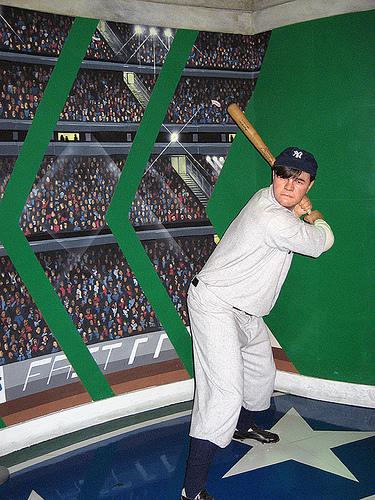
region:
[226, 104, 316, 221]
the statue is a baseball player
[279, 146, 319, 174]
the statue has a hat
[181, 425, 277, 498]
the statue is wearing shoes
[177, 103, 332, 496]
the statue is of a famous player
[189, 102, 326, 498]
the statue is on a batters position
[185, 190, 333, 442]
the uniform is white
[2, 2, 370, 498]
the scene takes place indoors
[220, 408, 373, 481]
the star image on the ground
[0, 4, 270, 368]
the image is of fans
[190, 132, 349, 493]
A badseball player in white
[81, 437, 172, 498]
A decorated baseball pitch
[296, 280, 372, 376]
A green pitch wall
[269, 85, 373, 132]
A green pitch wall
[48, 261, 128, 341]
Lots of people in the studium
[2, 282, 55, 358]
Lots of people in the studium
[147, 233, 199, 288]
Lots of people in the studium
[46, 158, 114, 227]
Lots of people in the studium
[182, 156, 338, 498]
wax figure of babe ruth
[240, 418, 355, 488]
left foot on white star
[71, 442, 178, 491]
blue floor where figure is on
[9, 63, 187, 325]
picture of fans in the stands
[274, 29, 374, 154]
green wall behind the figure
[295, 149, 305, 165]
baseball team logo on hat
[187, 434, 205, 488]
long blue socks on right leg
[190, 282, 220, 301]
black belt on waist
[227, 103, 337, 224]
bat in back of shoulder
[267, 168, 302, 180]
hair over right eye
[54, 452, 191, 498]
The floor is the color blue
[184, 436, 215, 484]
The man has on blue socks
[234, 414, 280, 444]
The man has on a shoe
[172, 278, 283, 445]
The man is wearing white pants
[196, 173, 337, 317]
The man has on a white top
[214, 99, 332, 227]
The man is holding a bat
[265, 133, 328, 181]
The man is wearing a hat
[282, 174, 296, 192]
The nose of the man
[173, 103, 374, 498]
The man is a wax figure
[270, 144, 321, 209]
The head of the man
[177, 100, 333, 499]
man holding baseball bat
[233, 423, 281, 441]
Black baseball shoe on man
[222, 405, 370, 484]
White star on floor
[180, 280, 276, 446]
White baseball pants on man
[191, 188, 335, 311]
White baseball shirt on man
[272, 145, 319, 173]
Blue baseball cap on man's head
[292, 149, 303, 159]
White baseball logo on cap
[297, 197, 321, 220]
Hands gripping baseball bat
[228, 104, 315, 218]
Tan baseball bat in man's hands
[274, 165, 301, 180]
Brown hair hanging in face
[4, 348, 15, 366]
spectator sitting in stands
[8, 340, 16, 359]
spectator sitting in stands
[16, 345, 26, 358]
spectator sitting in stands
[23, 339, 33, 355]
spectator sitting in stands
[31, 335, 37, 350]
spectator sitting in stands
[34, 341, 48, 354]
spectator sitting in stands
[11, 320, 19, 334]
spectator sitting in stands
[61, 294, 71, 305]
spectator sitting in stands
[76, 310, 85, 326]
spectator sitting in stands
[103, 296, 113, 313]
spectator sitting in stands